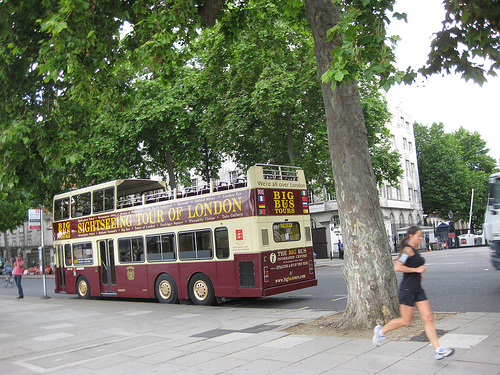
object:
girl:
[373, 226, 453, 360]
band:
[398, 252, 409, 264]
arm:
[395, 246, 412, 273]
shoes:
[373, 325, 388, 346]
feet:
[434, 348, 454, 360]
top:
[403, 245, 425, 290]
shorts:
[399, 284, 428, 307]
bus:
[52, 163, 317, 306]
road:
[0, 267, 499, 309]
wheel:
[189, 275, 216, 305]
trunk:
[306, 0, 402, 325]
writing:
[76, 196, 241, 234]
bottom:
[57, 264, 316, 295]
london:
[1, 1, 500, 374]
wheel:
[75, 275, 91, 299]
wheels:
[155, 274, 177, 302]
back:
[194, 172, 314, 304]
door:
[97, 239, 117, 296]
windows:
[213, 226, 231, 261]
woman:
[12, 252, 23, 298]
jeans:
[13, 275, 24, 296]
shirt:
[12, 260, 24, 275]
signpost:
[28, 209, 47, 296]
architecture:
[4, 101, 430, 266]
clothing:
[397, 245, 428, 307]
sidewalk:
[2, 298, 498, 374]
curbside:
[6, 292, 500, 316]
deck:
[53, 164, 303, 220]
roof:
[55, 178, 167, 201]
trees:
[1, 2, 409, 323]